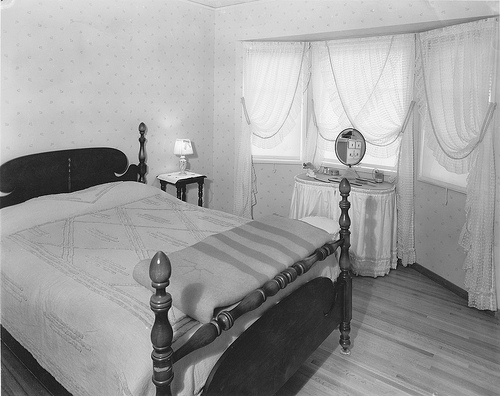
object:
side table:
[155, 169, 210, 207]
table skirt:
[288, 176, 404, 279]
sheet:
[0, 180, 259, 395]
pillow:
[95, 180, 160, 211]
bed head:
[0, 146, 137, 207]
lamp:
[170, 137, 196, 178]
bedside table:
[157, 139, 205, 210]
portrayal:
[155, 110, 226, 202]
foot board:
[199, 272, 342, 395]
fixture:
[338, 166, 362, 178]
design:
[14, 14, 176, 125]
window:
[303, 44, 410, 175]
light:
[323, 53, 399, 129]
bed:
[0, 125, 356, 394]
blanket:
[130, 213, 336, 323]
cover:
[8, 177, 199, 372]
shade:
[183, 139, 199, 161]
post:
[335, 177, 353, 356]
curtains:
[217, 17, 499, 312]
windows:
[236, 35, 309, 165]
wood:
[345, 322, 497, 385]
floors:
[0, 265, 500, 396]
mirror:
[333, 128, 369, 172]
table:
[289, 174, 404, 276]